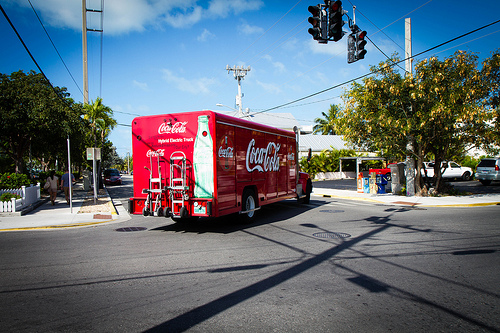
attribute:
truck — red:
[129, 108, 313, 227]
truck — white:
[415, 158, 473, 182]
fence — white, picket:
[2, 181, 42, 216]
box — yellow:
[368, 174, 378, 194]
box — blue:
[376, 174, 387, 193]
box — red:
[356, 170, 362, 190]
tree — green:
[315, 51, 499, 194]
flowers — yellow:
[321, 48, 498, 148]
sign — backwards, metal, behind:
[87, 146, 100, 161]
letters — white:
[242, 136, 282, 172]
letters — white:
[157, 118, 189, 136]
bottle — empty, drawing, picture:
[192, 114, 214, 199]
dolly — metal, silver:
[143, 149, 163, 218]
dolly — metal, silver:
[168, 148, 187, 218]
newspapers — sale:
[355, 173, 384, 184]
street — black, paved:
[3, 170, 494, 327]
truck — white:
[474, 155, 500, 184]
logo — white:
[145, 147, 167, 159]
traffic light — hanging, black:
[305, 3, 330, 45]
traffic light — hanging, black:
[329, 0, 345, 40]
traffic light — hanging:
[355, 29, 367, 60]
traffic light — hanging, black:
[347, 32, 355, 60]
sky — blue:
[1, 1, 497, 148]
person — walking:
[43, 168, 61, 206]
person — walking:
[62, 166, 77, 205]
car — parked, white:
[105, 168, 124, 187]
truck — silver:
[401, 157, 413, 172]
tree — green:
[2, 66, 53, 161]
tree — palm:
[80, 97, 113, 130]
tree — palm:
[94, 116, 116, 156]